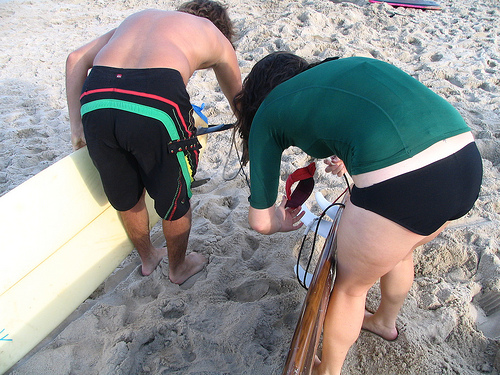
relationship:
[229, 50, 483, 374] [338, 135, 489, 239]
people has bottoms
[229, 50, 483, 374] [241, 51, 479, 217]
people has green shirt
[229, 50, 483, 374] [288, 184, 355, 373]
people has surfboard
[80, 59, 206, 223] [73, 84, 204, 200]
bottoms has stripes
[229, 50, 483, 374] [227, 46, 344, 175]
people hair down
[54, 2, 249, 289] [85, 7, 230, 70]
man has no shirt on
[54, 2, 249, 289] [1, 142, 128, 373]
man holding surf board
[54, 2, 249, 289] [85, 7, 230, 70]
man has no shirt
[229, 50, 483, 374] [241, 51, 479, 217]
people wearing green shirt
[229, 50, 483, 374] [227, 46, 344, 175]
people with brown hair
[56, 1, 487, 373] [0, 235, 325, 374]
people with surfboards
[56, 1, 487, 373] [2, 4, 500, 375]
people on beach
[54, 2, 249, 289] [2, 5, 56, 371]
person on left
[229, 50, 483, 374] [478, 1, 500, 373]
people on right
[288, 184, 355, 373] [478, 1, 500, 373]
surfboard on right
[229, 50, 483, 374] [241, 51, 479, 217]
people has green top